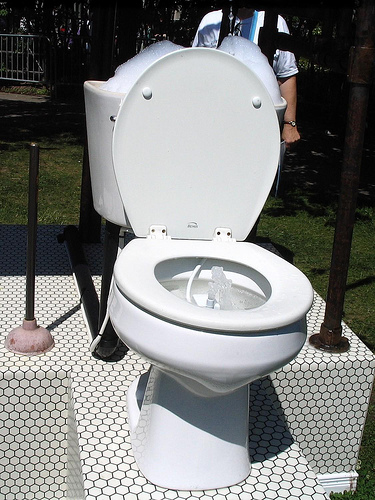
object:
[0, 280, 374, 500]
tile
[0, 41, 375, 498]
restroom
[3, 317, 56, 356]
sponger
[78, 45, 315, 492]
toilet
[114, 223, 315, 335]
seat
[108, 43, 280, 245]
lid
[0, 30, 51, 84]
railing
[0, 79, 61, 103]
sidewalk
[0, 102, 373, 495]
grass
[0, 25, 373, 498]
display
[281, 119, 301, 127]
watch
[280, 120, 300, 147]
hand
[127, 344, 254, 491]
base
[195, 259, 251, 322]
water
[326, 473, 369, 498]
weeds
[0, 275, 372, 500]
floor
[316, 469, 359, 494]
baseboard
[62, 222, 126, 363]
pipe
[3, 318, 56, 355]
plunger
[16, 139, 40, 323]
handle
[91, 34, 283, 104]
soap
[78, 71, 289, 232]
tank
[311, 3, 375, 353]
pipe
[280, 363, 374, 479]
floor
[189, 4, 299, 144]
person